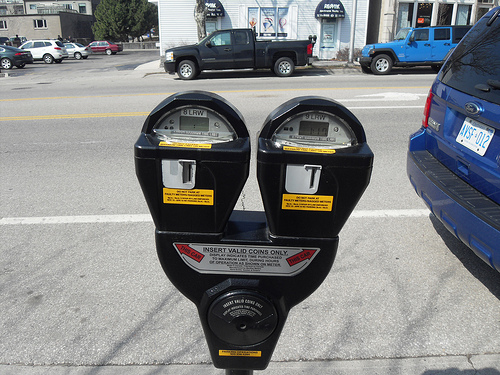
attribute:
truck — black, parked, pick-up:
[161, 26, 314, 77]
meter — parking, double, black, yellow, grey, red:
[131, 88, 378, 374]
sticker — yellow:
[160, 139, 213, 151]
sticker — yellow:
[283, 144, 337, 156]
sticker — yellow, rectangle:
[161, 188, 215, 207]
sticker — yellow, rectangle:
[279, 193, 335, 213]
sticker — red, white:
[174, 238, 320, 278]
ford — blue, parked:
[403, 2, 495, 279]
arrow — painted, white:
[337, 88, 429, 104]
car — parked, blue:
[360, 25, 469, 74]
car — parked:
[0, 46, 32, 72]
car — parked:
[88, 38, 121, 56]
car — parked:
[18, 38, 70, 65]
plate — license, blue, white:
[458, 117, 495, 156]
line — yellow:
[1, 109, 152, 123]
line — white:
[2, 206, 430, 228]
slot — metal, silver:
[178, 159, 194, 186]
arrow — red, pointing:
[174, 240, 205, 266]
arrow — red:
[286, 246, 316, 267]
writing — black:
[164, 193, 213, 200]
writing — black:
[284, 198, 332, 206]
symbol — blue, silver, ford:
[465, 102, 483, 116]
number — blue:
[483, 133, 491, 150]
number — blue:
[475, 130, 481, 145]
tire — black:
[177, 58, 197, 81]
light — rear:
[305, 42, 312, 55]